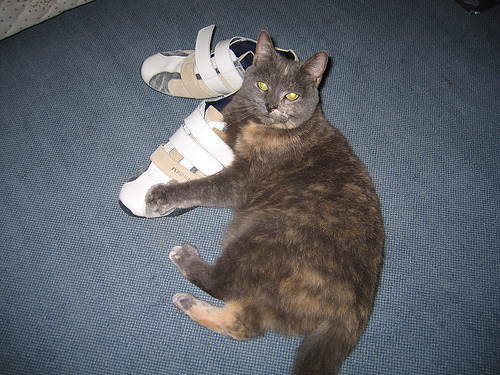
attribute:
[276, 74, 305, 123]
eye — green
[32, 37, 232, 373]
carpet — blue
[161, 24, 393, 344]
cat — furry, gray, tan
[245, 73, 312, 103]
eyes — yellow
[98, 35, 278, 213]
sandals — white, tan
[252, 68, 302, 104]
eyes — yellow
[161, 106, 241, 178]
straps — white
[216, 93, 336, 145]
whiskers — long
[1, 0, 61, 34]
fabric — white, pink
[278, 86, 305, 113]
eye — yellow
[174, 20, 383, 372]
cat — gray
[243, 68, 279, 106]
eye — yellow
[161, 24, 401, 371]
cat — gray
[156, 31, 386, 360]
cat — gray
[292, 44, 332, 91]
ear — large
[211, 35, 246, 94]
strap — white